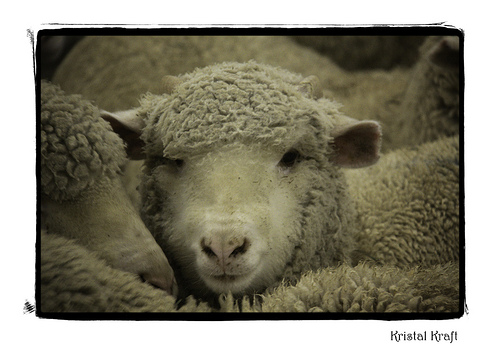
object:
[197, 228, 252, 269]
nose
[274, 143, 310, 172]
eye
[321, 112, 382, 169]
ear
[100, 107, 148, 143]
ear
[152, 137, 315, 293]
face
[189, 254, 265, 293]
mouth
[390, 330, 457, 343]
words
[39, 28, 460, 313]
sheep herd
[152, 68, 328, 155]
forehead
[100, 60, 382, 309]
animal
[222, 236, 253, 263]
nostril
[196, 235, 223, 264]
nostril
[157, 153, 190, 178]
eye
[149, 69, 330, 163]
wool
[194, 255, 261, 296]
mouth